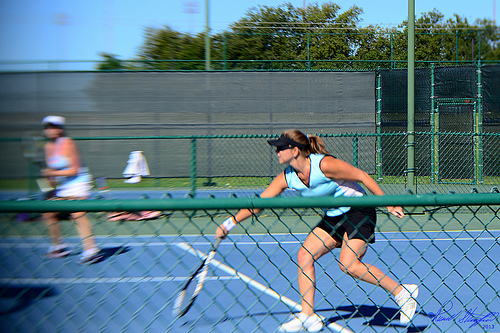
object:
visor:
[266, 134, 295, 147]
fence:
[0, 187, 499, 332]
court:
[0, 230, 497, 332]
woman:
[211, 129, 421, 332]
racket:
[170, 227, 233, 319]